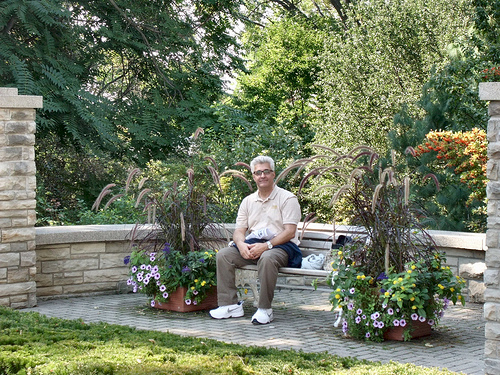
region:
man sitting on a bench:
[201, 133, 296, 330]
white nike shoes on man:
[215, 304, 274, 326]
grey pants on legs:
[211, 240, 282, 310]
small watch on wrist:
[263, 241, 274, 252]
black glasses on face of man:
[247, 167, 274, 178]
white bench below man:
[296, 258, 343, 286]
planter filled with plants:
[328, 250, 462, 356]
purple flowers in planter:
[343, 300, 396, 330]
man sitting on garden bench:
[209, 148, 299, 322]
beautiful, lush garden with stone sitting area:
[5, 3, 490, 374]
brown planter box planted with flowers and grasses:
[329, 157, 465, 337]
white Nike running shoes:
[208, 302, 273, 325]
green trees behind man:
[6, 30, 493, 210]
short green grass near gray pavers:
[0, 308, 372, 374]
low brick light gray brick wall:
[39, 225, 491, 305]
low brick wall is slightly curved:
[39, 220, 489, 307]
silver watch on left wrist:
[262, 239, 276, 251]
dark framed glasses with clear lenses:
[250, 169, 271, 177]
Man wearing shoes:
[208, 300, 278, 325]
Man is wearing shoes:
[207, 302, 277, 327]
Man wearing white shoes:
[202, 299, 278, 327]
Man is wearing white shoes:
[207, 298, 279, 328]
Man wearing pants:
[217, 240, 292, 310]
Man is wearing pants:
[214, 238, 293, 315]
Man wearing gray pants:
[207, 239, 294, 316]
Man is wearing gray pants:
[211, 242, 294, 312]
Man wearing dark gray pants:
[212, 242, 290, 310]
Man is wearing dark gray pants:
[210, 243, 293, 312]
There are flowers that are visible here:
[145, 250, 167, 302]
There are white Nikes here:
[253, 307, 275, 355]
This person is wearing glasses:
[257, 163, 274, 177]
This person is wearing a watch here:
[262, 245, 272, 261]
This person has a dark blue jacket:
[281, 243, 292, 270]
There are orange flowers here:
[461, 125, 468, 152]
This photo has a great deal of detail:
[128, 83, 304, 324]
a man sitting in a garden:
[84, 121, 469, 349]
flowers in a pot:
[323, 254, 463, 339]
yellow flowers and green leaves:
[378, 266, 433, 305]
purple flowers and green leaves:
[341, 300, 380, 342]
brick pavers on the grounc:
[173, 319, 333, 341]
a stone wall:
[27, 217, 132, 296]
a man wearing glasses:
[248, 164, 278, 174]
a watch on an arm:
[263, 241, 276, 249]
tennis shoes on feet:
[206, 299, 281, 326]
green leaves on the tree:
[341, 71, 375, 110]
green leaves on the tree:
[384, 109, 437, 178]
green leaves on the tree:
[261, 4, 303, 70]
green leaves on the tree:
[185, 50, 268, 133]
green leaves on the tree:
[31, 66, 112, 130]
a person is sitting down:
[210, 150, 304, 332]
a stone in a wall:
[38, 259, 103, 271]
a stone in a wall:
[32, 282, 62, 297]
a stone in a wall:
[9, 264, 31, 281]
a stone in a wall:
[21, 247, 41, 269]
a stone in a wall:
[2, 251, 22, 269]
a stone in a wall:
[474, 264, 498, 289]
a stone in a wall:
[482, 305, 499, 323]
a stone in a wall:
[483, 322, 498, 339]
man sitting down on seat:
[159, 137, 366, 309]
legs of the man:
[199, 248, 293, 311]